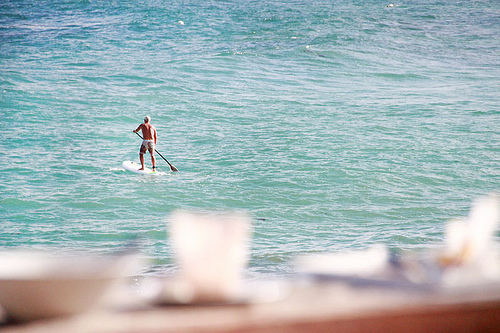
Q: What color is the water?
A: Blue.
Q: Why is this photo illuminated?
A: Sunlight.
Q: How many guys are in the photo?
A: One.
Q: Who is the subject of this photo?
A: The man.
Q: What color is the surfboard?
A: White.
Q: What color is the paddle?
A: Black.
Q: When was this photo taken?
A: During the day.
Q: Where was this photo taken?
A: In the ocean.